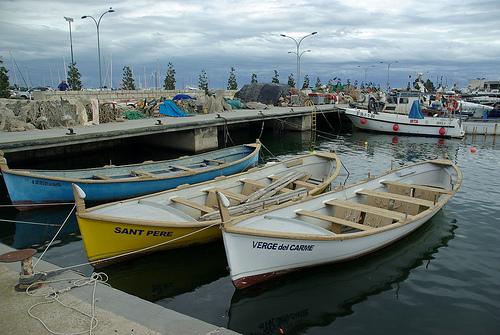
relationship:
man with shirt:
[404, 91, 430, 121] [409, 100, 426, 121]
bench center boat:
[297, 176, 443, 232] [211, 154, 461, 282]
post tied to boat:
[2, 245, 41, 295] [211, 154, 461, 282]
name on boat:
[250, 239, 314, 251] [211, 154, 461, 282]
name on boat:
[114, 227, 173, 239] [75, 147, 345, 267]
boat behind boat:
[344, 102, 465, 138] [75, 147, 345, 267]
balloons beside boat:
[355, 116, 452, 140] [340, 100, 461, 136]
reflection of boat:
[234, 212, 462, 323] [226, 164, 461, 288]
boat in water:
[2, 145, 264, 210] [7, 116, 496, 333]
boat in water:
[414, 106, 494, 133] [7, 116, 496, 333]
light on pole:
[283, 30, 313, 52] [290, 37, 302, 86]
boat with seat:
[211, 154, 461, 282] [291, 206, 371, 233]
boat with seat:
[211, 154, 463, 281] [335, 196, 405, 225]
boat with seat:
[211, 154, 461, 282] [358, 186, 432, 207]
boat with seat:
[211, 154, 461, 282] [381, 178, 450, 198]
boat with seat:
[211, 154, 463, 281] [385, 179, 447, 198]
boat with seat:
[211, 154, 461, 282] [382, 178, 442, 195]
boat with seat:
[211, 154, 461, 282] [359, 190, 435, 210]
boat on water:
[344, 102, 465, 142] [7, 116, 496, 333]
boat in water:
[211, 154, 463, 281] [7, 116, 496, 333]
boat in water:
[75, 147, 345, 267] [7, 116, 496, 333]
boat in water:
[344, 102, 465, 138] [2, 132, 484, 332]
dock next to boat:
[0, 100, 340, 170] [2, 143, 262, 211]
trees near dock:
[1, 54, 385, 97] [0, 100, 340, 170]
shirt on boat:
[409, 100, 426, 121] [338, 103, 468, 139]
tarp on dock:
[155, 98, 195, 117] [0, 100, 340, 170]